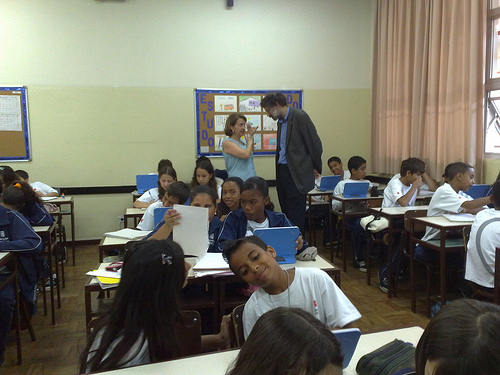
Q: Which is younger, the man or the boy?
A: The boy is younger than the man.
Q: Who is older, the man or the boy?
A: The man is older than the boy.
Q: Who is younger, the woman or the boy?
A: The boy is younger than the woman.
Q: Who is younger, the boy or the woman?
A: The boy is younger than the woman.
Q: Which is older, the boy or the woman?
A: The woman is older than the boy.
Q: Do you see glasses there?
A: No, there are no glasses.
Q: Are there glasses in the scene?
A: No, there are no glasses.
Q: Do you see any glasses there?
A: No, there are no glasses.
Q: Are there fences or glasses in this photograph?
A: No, there are no glasses or fences.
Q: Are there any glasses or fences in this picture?
A: No, there are no glasses or fences.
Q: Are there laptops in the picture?
A: Yes, there is a laptop.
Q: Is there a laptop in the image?
A: Yes, there is a laptop.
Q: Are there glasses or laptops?
A: Yes, there is a laptop.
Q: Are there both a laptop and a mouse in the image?
A: No, there is a laptop but no computer mice.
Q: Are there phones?
A: No, there are no phones.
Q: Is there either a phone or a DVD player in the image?
A: No, there are no phones or DVD players.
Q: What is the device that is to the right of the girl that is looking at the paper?
A: The device is a laptop.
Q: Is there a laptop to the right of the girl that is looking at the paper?
A: Yes, there is a laptop to the right of the girl.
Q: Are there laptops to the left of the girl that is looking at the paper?
A: No, the laptop is to the right of the girl.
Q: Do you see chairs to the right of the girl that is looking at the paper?
A: No, there is a laptop to the right of the girl.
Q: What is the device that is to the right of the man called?
A: The device is a laptop.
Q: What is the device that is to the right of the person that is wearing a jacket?
A: The device is a laptop.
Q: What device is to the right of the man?
A: The device is a laptop.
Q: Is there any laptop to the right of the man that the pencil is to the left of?
A: Yes, there is a laptop to the right of the man.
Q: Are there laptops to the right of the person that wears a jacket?
A: Yes, there is a laptop to the right of the man.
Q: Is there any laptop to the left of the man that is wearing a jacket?
A: No, the laptop is to the right of the man.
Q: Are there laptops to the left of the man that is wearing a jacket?
A: No, the laptop is to the right of the man.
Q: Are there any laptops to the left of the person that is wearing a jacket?
A: No, the laptop is to the right of the man.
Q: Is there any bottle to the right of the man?
A: No, there is a laptop to the right of the man.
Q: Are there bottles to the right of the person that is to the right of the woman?
A: No, there is a laptop to the right of the man.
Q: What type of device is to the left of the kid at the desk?
A: The device is a laptop.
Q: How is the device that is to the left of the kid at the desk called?
A: The device is a laptop.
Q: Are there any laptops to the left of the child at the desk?
A: Yes, there is a laptop to the left of the child.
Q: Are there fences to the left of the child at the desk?
A: No, there is a laptop to the left of the child.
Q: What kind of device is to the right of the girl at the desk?
A: The device is a laptop.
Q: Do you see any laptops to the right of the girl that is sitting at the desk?
A: Yes, there is a laptop to the right of the girl.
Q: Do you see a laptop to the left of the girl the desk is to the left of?
A: No, the laptop is to the right of the girl.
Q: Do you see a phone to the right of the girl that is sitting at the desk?
A: No, there is a laptop to the right of the girl.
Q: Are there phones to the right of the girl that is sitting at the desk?
A: No, there is a laptop to the right of the girl.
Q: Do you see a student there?
A: Yes, there is a student.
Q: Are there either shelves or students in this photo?
A: Yes, there is a student.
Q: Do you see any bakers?
A: No, there are no bakers.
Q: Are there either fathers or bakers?
A: No, there are no bakers or fathers.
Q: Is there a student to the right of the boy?
A: Yes, there is a student to the right of the boy.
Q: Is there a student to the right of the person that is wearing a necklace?
A: Yes, there is a student to the right of the boy.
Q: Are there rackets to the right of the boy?
A: No, there is a student to the right of the boy.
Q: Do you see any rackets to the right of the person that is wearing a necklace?
A: No, there is a student to the right of the boy.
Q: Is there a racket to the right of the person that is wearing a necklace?
A: No, there is a student to the right of the boy.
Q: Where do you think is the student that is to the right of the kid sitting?
A: The student is sitting at the desk.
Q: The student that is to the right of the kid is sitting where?
A: The student is sitting at the desk.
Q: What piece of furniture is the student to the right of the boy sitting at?
A: The student is sitting at the desk.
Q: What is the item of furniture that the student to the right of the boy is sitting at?
A: The piece of furniture is a desk.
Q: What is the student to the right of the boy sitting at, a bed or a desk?
A: The student is sitting at a desk.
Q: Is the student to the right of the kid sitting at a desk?
A: Yes, the student is sitting at a desk.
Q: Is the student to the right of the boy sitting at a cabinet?
A: No, the student is sitting at a desk.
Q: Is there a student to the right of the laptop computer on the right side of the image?
A: Yes, there is a student to the right of the laptop computer.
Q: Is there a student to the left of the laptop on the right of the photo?
A: No, the student is to the right of the laptop.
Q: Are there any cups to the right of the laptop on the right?
A: No, there is a student to the right of the laptop computer.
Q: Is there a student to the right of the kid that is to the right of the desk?
A: Yes, there is a student to the right of the kid.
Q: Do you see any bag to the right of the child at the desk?
A: No, there is a student to the right of the kid.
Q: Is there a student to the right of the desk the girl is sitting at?
A: Yes, there is a student to the right of the desk.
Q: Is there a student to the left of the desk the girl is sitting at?
A: No, the student is to the right of the desk.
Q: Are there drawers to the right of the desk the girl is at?
A: No, there is a student to the right of the desk.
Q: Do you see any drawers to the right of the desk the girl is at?
A: No, there is a student to the right of the desk.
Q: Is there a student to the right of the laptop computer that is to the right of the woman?
A: Yes, there is a student to the right of the laptop.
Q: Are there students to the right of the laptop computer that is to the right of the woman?
A: Yes, there is a student to the right of the laptop.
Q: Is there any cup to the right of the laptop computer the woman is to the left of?
A: No, there is a student to the right of the laptop.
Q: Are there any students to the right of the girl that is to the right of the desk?
A: Yes, there is a student to the right of the girl.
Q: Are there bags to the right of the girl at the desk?
A: No, there is a student to the right of the girl.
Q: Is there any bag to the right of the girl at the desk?
A: No, there is a student to the right of the girl.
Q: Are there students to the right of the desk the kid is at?
A: Yes, there is a student to the right of the desk.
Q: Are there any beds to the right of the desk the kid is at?
A: No, there is a student to the right of the desk.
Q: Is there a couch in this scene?
A: No, there are no couches.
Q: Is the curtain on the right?
A: Yes, the curtain is on the right of the image.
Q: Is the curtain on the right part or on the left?
A: The curtain is on the right of the image.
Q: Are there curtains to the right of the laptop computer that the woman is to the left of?
A: Yes, there is a curtain to the right of the laptop.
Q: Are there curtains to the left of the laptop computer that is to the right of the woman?
A: No, the curtain is to the right of the laptop computer.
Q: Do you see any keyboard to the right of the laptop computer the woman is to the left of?
A: No, there is a curtain to the right of the laptop.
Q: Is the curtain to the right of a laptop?
A: Yes, the curtain is to the right of a laptop.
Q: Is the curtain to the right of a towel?
A: No, the curtain is to the right of a laptop.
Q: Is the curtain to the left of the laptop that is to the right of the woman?
A: No, the curtain is to the right of the laptop.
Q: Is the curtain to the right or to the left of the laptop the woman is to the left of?
A: The curtain is to the right of the laptop.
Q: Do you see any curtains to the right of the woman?
A: Yes, there is a curtain to the right of the woman.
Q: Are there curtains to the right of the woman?
A: Yes, there is a curtain to the right of the woman.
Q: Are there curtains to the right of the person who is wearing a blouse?
A: Yes, there is a curtain to the right of the woman.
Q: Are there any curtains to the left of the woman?
A: No, the curtain is to the right of the woman.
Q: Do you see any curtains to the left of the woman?
A: No, the curtain is to the right of the woman.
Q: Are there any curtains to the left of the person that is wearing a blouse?
A: No, the curtain is to the right of the woman.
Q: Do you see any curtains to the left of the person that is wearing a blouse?
A: No, the curtain is to the right of the woman.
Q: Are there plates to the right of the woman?
A: No, there is a curtain to the right of the woman.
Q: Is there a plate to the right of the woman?
A: No, there is a curtain to the right of the woman.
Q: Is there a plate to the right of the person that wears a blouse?
A: No, there is a curtain to the right of the woman.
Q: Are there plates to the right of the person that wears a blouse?
A: No, there is a curtain to the right of the woman.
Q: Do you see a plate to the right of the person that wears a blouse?
A: No, there is a curtain to the right of the woman.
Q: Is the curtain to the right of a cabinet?
A: No, the curtain is to the right of the woman.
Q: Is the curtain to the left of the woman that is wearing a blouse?
A: No, the curtain is to the right of the woman.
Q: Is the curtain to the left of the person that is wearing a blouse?
A: No, the curtain is to the right of the woman.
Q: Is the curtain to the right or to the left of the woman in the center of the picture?
A: The curtain is to the right of the woman.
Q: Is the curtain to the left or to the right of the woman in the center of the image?
A: The curtain is to the right of the woman.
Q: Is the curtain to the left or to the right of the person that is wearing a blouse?
A: The curtain is to the right of the woman.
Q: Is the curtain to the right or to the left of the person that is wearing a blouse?
A: The curtain is to the right of the woman.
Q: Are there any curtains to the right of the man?
A: Yes, there is a curtain to the right of the man.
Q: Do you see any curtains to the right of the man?
A: Yes, there is a curtain to the right of the man.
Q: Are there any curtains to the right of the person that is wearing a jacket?
A: Yes, there is a curtain to the right of the man.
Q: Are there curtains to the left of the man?
A: No, the curtain is to the right of the man.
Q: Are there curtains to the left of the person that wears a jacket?
A: No, the curtain is to the right of the man.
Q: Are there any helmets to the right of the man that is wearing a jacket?
A: No, there is a curtain to the right of the man.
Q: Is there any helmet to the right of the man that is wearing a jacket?
A: No, there is a curtain to the right of the man.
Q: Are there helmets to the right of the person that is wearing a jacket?
A: No, there is a curtain to the right of the man.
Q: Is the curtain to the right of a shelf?
A: No, the curtain is to the right of the man.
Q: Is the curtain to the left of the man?
A: No, the curtain is to the right of the man.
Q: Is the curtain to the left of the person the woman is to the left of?
A: No, the curtain is to the right of the man.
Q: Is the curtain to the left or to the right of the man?
A: The curtain is to the right of the man.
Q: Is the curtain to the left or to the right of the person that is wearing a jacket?
A: The curtain is to the right of the man.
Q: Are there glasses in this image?
A: No, there are no glasses.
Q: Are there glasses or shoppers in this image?
A: No, there are no glasses or shoppers.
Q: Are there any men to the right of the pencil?
A: Yes, there is a man to the right of the pencil.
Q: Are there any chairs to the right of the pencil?
A: No, there is a man to the right of the pencil.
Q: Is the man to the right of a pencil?
A: Yes, the man is to the right of a pencil.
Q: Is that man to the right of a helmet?
A: No, the man is to the right of a pencil.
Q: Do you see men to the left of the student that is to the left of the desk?
A: Yes, there is a man to the left of the student.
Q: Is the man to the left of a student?
A: Yes, the man is to the left of a student.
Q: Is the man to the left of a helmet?
A: No, the man is to the left of a student.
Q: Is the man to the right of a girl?
A: Yes, the man is to the right of a girl.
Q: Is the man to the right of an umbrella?
A: No, the man is to the right of a girl.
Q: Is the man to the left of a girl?
A: No, the man is to the right of a girl.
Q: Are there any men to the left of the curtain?
A: Yes, there is a man to the left of the curtain.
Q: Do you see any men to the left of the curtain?
A: Yes, there is a man to the left of the curtain.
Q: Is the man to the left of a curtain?
A: Yes, the man is to the left of a curtain.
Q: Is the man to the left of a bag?
A: No, the man is to the left of a curtain.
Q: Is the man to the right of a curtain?
A: No, the man is to the left of a curtain.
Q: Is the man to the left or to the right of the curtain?
A: The man is to the left of the curtain.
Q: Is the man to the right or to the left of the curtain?
A: The man is to the left of the curtain.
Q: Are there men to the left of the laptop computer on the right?
A: Yes, there is a man to the left of the laptop.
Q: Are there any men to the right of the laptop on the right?
A: No, the man is to the left of the laptop.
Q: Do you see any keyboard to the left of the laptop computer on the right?
A: No, there is a man to the left of the laptop.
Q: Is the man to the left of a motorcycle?
A: No, the man is to the left of a laptop.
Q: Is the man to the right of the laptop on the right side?
A: No, the man is to the left of the laptop.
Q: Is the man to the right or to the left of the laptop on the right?
A: The man is to the left of the laptop.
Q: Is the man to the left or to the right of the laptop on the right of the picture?
A: The man is to the left of the laptop.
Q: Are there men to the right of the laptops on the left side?
A: Yes, there is a man to the right of the laptops.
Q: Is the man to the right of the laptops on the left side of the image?
A: Yes, the man is to the right of the laptops.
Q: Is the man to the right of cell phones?
A: No, the man is to the right of the laptops.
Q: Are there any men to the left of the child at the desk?
A: Yes, there is a man to the left of the kid.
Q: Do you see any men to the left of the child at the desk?
A: Yes, there is a man to the left of the kid.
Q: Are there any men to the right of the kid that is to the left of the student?
A: No, the man is to the left of the child.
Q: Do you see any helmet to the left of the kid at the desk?
A: No, there is a man to the left of the child.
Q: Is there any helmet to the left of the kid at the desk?
A: No, there is a man to the left of the child.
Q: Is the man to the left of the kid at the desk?
A: Yes, the man is to the left of the kid.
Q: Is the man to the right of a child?
A: No, the man is to the left of a child.